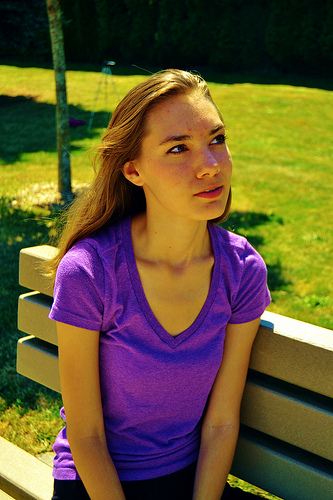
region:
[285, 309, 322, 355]
white top of bench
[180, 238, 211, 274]
lines in woman's neck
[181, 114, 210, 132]
acne on girl's face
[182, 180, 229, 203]
red lipstick on girl's lips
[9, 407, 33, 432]
brown grass on ground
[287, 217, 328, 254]
green shrub on ground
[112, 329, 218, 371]
break in tee shirt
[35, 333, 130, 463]
girl's tanned arm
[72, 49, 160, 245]
shiny blond long hair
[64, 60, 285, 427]
girl sitting on bench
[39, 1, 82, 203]
the truck of a tree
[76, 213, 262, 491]
a v-neck purple T-shirt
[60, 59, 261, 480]
a young woman wearing a purple T-shirt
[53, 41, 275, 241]
a young woman with dark eyes and long blond hair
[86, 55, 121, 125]
a tripod standing on the lawn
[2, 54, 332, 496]
a young woman sitting on a bench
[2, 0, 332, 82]
a row of green trees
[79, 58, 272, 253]
a young woman with fair skin and some pimples on her face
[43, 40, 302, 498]
young woman wearing a purple shirt sitting on a bench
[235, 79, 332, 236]
a well mowed green lawn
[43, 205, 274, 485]
The girl's purple shirt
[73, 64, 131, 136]
The tripod behind the girl's head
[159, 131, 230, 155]
Both of the girl's eyes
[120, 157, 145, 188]
The right ear of the girl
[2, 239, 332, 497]
The bench the girl is sitting on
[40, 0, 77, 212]
The single tree trunk in the background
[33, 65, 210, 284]
The hair of the girl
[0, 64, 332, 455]
The grass field behind the girl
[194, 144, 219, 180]
The nose of the girl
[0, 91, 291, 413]
The shadow of the trees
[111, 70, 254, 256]
girl looking up and to the right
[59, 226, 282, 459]
girl in purple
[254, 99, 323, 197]
green grass behind bench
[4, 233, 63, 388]
brown bench beneath girl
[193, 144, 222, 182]
nose of the girl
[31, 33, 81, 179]
stem of tree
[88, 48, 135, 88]
camera tripod in background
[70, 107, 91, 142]
Purple thing next to tripod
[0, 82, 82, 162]
shadow in background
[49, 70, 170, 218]
brown hair of girl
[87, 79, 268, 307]
Girl looking up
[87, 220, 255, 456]
Purple tshirt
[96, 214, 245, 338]
V neck shirt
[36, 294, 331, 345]
Short sleeves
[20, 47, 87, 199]
Skinny tree trunk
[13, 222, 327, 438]
Park bench to sit on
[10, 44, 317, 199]
Bright green grass in the background.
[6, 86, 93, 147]
A shadow cast from a tree.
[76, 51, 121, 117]
A tripod for a camera.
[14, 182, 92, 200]
Small white flowers under a tree